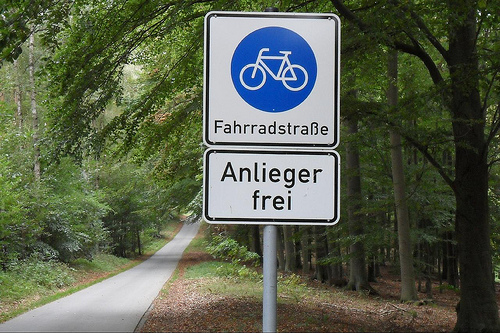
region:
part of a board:
[214, 105, 261, 162]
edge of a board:
[206, 210, 266, 247]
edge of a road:
[157, 272, 178, 301]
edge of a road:
[166, 255, 178, 271]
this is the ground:
[189, 286, 233, 331]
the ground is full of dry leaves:
[184, 290, 209, 330]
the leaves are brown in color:
[175, 300, 195, 326]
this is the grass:
[191, 262, 213, 278]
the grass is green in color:
[193, 265, 208, 275]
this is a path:
[26, 205, 191, 332]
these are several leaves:
[363, 8, 494, 315]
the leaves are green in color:
[61, 46, 102, 97]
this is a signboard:
[199, 10, 341, 225]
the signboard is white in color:
[218, 26, 237, 43]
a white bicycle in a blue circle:
[223, 24, 319, 117]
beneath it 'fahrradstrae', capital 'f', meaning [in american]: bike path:
[212, 117, 330, 142]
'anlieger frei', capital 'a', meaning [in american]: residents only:
[214, 156, 328, 215]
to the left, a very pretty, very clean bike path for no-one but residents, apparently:
[1, 200, 204, 332]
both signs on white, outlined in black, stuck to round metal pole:
[198, 6, 345, 332]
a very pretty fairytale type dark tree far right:
[337, 0, 499, 332]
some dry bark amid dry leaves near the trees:
[280, 278, 457, 331]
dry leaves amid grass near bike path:
[130, 228, 259, 332]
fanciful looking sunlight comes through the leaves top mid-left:
[87, 44, 162, 126]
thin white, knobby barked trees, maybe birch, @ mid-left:
[0, 0, 47, 206]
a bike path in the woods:
[0, 270, 154, 332]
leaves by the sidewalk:
[129, 302, 206, 329]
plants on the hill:
[0, 251, 77, 295]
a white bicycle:
[238, 39, 310, 98]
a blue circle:
[231, 17, 317, 116]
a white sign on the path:
[198, 7, 337, 235]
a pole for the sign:
[252, 222, 284, 332]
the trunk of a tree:
[443, 195, 498, 330]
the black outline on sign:
[206, 212, 333, 224]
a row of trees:
[287, 234, 452, 285]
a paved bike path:
[11, 198, 218, 330]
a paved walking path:
[6, 198, 213, 328]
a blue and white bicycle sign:
[200, 12, 338, 149]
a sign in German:
[200, 7, 342, 149]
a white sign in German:
[198, 150, 340, 227]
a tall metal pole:
[256, 224, 281, 331]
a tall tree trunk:
[426, 2, 492, 322]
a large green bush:
[41, 184, 102, 261]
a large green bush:
[0, 185, 47, 259]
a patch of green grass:
[189, 257, 299, 294]